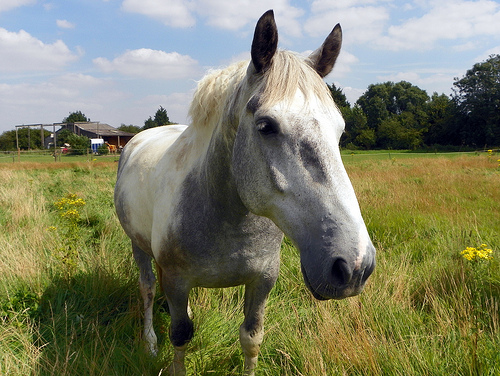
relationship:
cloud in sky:
[92, 48, 201, 85] [5, 3, 495, 128]